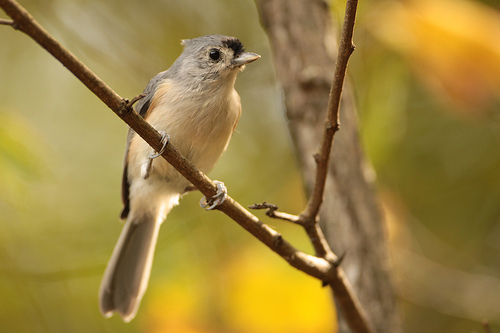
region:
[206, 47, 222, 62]
the black eye of the bird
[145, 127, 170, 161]
the claw of a bird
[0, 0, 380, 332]
a brown tree branch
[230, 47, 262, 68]
the gray beak of a bird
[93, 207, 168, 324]
the tail of a bird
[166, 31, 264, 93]
the head of a bird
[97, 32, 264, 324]
a bird on a branch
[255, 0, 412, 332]
the brown trunk of a tree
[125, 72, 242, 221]
the white underside of a bird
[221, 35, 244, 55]
black feathers on the bird's head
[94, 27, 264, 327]
a bird on a limb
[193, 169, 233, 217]
bird foot clutching a limb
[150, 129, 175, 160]
bird foot clutching a limb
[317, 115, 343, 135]
a location of a bud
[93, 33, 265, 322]
a gray and white bird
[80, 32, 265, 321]
a grey and white bird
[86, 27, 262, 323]
a white and gray bird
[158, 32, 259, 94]
a bird with a black spot on its face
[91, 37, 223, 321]
A common bird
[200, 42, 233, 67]
a birds, beady black eye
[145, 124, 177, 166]
a small birds talons gripping a twig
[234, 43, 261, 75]
a birds beak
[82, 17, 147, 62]
excellent boheh in the background of this photo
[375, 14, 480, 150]
a blurred background is good photography skill to master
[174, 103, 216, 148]
cream colored feathers on this birds breast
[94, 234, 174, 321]
a birds tail feathers provide balance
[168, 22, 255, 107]
The bird is constantly on the lookout for danger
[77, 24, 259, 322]
A common bird sitting on a nearby twig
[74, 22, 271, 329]
Bird is grey and orange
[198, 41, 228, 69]
Bird black eye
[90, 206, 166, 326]
Long tail of bird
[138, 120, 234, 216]
Legs attached to a tree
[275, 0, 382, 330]
Branch is brown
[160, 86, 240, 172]
Brest of bird is orange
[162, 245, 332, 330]
Background is yellow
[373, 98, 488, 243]
Green leaves are blurry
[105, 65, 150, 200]
Wings are grey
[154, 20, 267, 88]
Head of bird is grey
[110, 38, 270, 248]
One bird is seen.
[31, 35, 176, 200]
Twig is brown color.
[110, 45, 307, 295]
Bird is grey and white color.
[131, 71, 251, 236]
Bird is sitting in the twig.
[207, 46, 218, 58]
Bird eye is black color.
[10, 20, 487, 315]
Day time picture.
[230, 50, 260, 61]
Bird has a small beak.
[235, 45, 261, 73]
Bird beak is grey color.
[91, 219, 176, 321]
Tail is grey color.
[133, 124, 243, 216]
Bird has two legs.